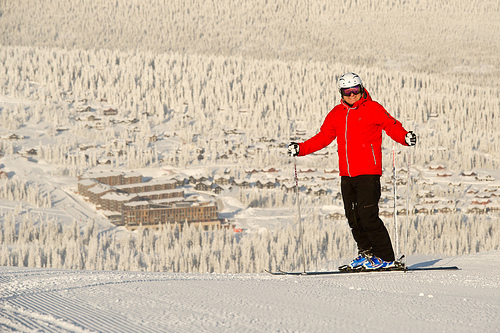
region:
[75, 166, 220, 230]
brown snow covered buildings below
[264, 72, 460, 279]
person skiing above a town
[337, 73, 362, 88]
the ski helmet is silver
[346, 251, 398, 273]
the skier's shoes are blue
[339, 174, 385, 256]
person has on black pants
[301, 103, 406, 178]
the jacket is orange with silver zippers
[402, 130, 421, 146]
glove is black and white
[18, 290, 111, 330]
straight lines in the snow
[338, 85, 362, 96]
snow goggles are black and tinted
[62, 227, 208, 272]
pine tree are white from snow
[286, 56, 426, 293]
A person in a red ski jacket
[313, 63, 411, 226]
A red ski jacket and black pants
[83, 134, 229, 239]
A ski lodge among the trees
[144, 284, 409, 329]
Snow is on the ground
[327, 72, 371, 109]
Person is wearing ski goggles and a helmet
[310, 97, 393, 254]
A red ski jacket and black ski pants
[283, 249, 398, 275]
Blue ski boots on black skis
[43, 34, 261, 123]
The trees are covered in snow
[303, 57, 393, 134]
Person is happy to be skiing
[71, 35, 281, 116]
So many trees all covered in snow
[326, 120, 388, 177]
A red nylon jacket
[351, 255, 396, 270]
Blue and white sneakers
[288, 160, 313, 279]
A long supporting pole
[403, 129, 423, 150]
Black and white gloves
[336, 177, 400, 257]
Black heavy nylon pants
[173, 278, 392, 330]
Grey and white snow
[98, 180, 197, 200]
Snow covered tall buildings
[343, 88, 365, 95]
Black wide eye glasses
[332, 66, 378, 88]
White and black helmet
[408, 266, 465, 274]
A black snow board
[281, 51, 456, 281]
person standing on white mountaintop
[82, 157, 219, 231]
buildings on flat area covered in snow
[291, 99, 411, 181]
bright red jacket of skier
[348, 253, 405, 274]
blue ski boots of skier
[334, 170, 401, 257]
black pants of skier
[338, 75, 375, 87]
white helmet of skier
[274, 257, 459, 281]
black skis of skier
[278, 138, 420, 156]
white gloves of the skier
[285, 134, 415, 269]
two ski poles of skier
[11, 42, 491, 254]
snow covered trees in the background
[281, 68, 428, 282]
Person on top of mountain snow sking.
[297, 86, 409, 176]
Person dressed in red jacket with hood.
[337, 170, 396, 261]
Person dressed in black pants.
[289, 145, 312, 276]
Person holding ski pole in hand.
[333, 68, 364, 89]
Person wearing silver safety helmet.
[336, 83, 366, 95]
Person wearing goggles over eyes.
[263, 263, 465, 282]
Skis attached to person's feet.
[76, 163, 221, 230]
Ski lodge at bottom of mountain.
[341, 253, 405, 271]
Person wearing blue ski shoes.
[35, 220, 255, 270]
Snow covered pine trees at bottom of mountain.